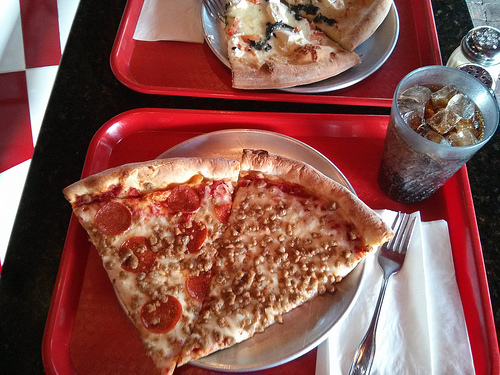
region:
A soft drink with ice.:
[378, 60, 494, 219]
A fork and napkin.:
[338, 195, 453, 372]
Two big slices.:
[46, 137, 383, 369]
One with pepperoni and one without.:
[77, 153, 382, 367]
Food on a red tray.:
[58, 115, 488, 368]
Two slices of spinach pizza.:
[203, 2, 406, 100]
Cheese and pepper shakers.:
[418, 20, 496, 111]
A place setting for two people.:
[67, 2, 489, 369]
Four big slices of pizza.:
[78, 1, 418, 373]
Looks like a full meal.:
[78, 2, 445, 366]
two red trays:
[61, 1, 464, 337]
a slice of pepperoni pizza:
[75, 125, 212, 342]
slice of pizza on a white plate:
[242, 122, 366, 372]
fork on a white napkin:
[352, 206, 447, 371]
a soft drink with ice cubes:
[381, 97, 498, 202]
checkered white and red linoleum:
[4, 4, 66, 174]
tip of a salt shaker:
[446, 15, 498, 72]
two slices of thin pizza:
[203, 2, 398, 76]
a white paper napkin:
[120, 3, 200, 49]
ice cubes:
[421, 86, 485, 140]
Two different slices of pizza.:
[58, 132, 377, 366]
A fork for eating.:
[343, 194, 423, 373]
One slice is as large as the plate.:
[49, 125, 379, 372]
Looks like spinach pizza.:
[188, 2, 397, 97]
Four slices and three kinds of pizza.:
[52, 2, 433, 364]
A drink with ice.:
[358, 56, 491, 219]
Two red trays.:
[64, 2, 488, 364]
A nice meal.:
[63, 5, 430, 370]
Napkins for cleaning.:
[313, 176, 480, 372]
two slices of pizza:
[60, 150, 382, 365]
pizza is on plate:
[55, 130, 391, 360]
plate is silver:
[45, 118, 383, 360]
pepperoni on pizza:
[66, 160, 256, 349]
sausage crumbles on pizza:
[234, 182, 356, 348]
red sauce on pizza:
[123, 186, 208, 232]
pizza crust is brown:
[61, 147, 386, 262]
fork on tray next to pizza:
[68, 91, 483, 371]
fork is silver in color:
[357, 205, 405, 372]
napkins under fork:
[341, 200, 426, 370]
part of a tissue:
[425, 327, 462, 364]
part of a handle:
[345, 317, 385, 373]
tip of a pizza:
[173, 355, 199, 373]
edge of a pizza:
[246, 298, 291, 345]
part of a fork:
[393, 212, 413, 259]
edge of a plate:
[285, 336, 320, 363]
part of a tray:
[340, 137, 363, 152]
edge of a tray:
[118, 108, 154, 130]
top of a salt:
[469, 32, 495, 59]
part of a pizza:
[257, 147, 300, 162]